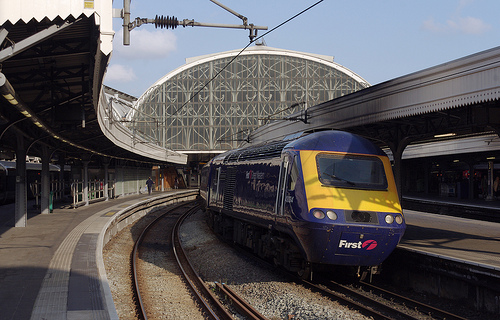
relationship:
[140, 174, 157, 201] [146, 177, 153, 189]
man wearing clothing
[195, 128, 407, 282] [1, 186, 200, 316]
train beside platform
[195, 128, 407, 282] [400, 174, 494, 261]
train in station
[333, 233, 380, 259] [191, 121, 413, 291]
logo on train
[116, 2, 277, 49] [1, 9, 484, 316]
holder over station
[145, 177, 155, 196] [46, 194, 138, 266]
man walking along platform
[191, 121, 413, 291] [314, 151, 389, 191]
train has window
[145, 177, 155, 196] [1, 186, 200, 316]
man walking on platform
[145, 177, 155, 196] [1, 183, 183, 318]
man walking on platform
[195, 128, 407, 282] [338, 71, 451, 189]
train at depo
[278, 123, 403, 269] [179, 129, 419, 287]
headlights on train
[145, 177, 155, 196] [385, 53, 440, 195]
man on station